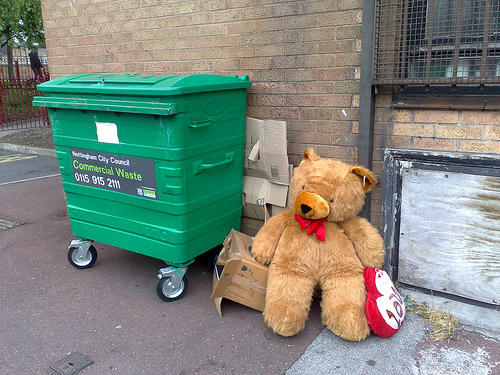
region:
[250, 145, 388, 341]
A teddy bear is brown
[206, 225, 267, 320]
A brown cardboard box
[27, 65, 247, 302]
A large green garbage bin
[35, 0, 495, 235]
Brown bricks on side of a building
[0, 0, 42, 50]
Green leaves on a tree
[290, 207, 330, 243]
Red ribbon on a teddy bear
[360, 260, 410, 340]
A red and white stuffed heart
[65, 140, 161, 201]
Black sticker on garbage bin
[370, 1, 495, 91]
Fence and bars over a window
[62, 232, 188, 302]
Two black round wheels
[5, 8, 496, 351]
a back alley area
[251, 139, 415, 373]
an oversized teddy bear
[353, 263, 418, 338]
a valentine's day decoration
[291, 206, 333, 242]
a red bow on the bear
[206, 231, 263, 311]
a discarded cardboard box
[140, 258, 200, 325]
a swiveling wheel for transit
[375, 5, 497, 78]
a metal grate over a window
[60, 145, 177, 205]
contact info for the waste company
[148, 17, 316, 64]
a beige brick wall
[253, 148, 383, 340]
Brown stuffed teddy bear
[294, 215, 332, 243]
Red ribbon around teddy bears neck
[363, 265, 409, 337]
Red and white heart shaped pillow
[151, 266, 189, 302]
Silver and black wheel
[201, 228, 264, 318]
Tan cardboard box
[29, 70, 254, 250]
Large green garbage can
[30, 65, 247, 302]
Green garbage on wheels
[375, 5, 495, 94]
Brown wire and bars on window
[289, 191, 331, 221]
Brown bear with an orange nose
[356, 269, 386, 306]
heart is leaning on bear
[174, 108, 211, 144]
the can is green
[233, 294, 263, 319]
the box is on the ground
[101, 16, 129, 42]
the building is tan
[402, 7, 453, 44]
the gate is on the window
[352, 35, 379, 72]
the pole is gray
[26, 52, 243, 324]
green trashcan next to a brick wall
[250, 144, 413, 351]
large stuffed bear with a red heart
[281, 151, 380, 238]
stuffed bear with a red ribbon around the neck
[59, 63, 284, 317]
boxes next to a trashcan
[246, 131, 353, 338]
boxes and a stuffed bear on the ground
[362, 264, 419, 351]
toy heart on the ground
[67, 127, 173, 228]
sign on the side of a trashcan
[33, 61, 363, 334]
stuffed bear, boxes, and a trashcan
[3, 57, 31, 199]
red fence in the background